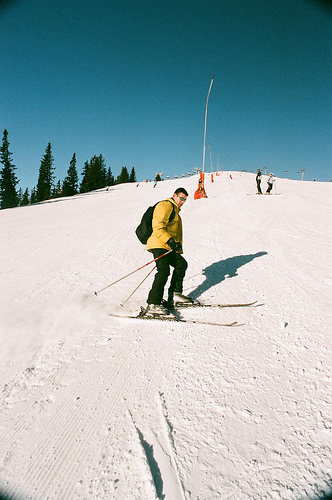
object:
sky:
[0, 1, 330, 189]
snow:
[0, 168, 330, 499]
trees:
[1, 129, 18, 212]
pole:
[198, 66, 217, 177]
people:
[145, 168, 276, 331]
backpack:
[135, 203, 155, 245]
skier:
[146, 187, 193, 314]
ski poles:
[92, 249, 173, 296]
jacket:
[146, 197, 183, 254]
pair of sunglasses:
[177, 194, 186, 202]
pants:
[146, 248, 188, 305]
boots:
[145, 304, 170, 316]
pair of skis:
[108, 299, 259, 326]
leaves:
[2, 132, 9, 157]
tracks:
[3, 336, 143, 500]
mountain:
[2, 171, 329, 500]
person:
[256, 167, 266, 197]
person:
[265, 173, 280, 196]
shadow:
[186, 251, 268, 299]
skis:
[246, 192, 265, 195]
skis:
[263, 193, 282, 196]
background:
[1, 127, 330, 211]